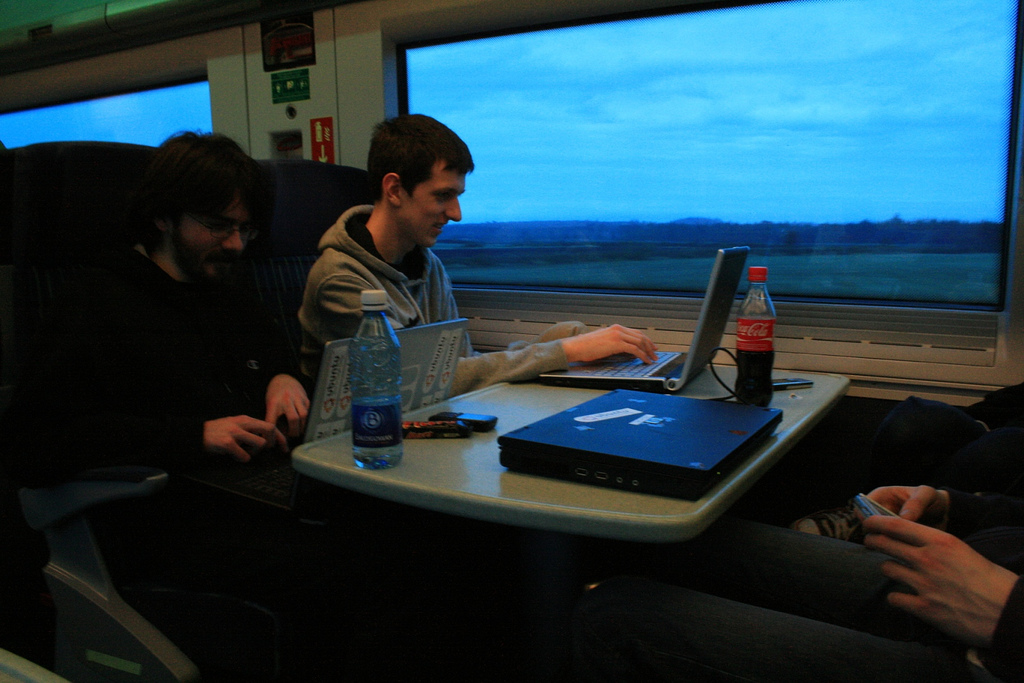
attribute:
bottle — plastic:
[333, 302, 494, 557]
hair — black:
[356, 103, 469, 212]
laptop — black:
[518, 253, 800, 487]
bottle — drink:
[730, 246, 785, 415]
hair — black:
[97, 120, 279, 309]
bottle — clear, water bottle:
[333, 270, 403, 482]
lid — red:
[724, 257, 783, 288]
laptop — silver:
[274, 304, 489, 443]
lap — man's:
[82, 414, 385, 536]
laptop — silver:
[478, 233, 747, 406]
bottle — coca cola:
[693, 229, 795, 405]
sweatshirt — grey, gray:
[285, 192, 590, 402]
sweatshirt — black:
[0, 250, 325, 575]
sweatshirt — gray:
[248, 168, 570, 406]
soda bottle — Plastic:
[733, 263, 779, 404]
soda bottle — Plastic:
[737, 257, 785, 404]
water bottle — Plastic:
[346, 283, 407, 467]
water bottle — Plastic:
[353, 283, 408, 469]